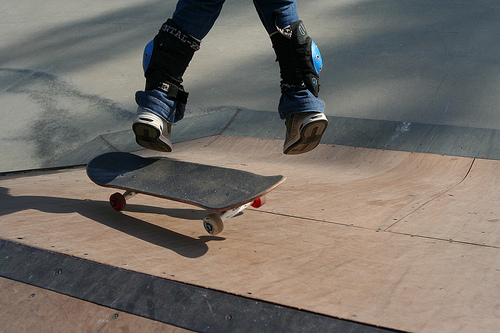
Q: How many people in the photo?
A: One.